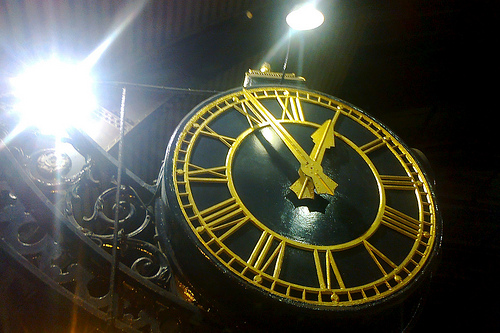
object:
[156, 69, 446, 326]
clock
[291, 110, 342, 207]
hand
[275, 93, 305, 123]
roman numeral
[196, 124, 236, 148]
roman numeral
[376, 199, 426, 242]
roman numeral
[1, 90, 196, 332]
mount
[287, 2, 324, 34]
light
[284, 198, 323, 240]
reflection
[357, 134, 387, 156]
number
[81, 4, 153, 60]
ray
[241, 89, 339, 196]
hand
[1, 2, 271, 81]
roof